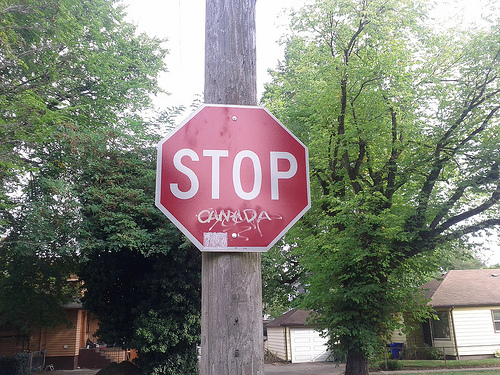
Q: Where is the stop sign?
A: On tree.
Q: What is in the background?
A: Houses.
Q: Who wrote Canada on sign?
A: A vandal.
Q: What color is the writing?
A: White.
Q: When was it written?
A: Recently.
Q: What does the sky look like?
A: Bright.